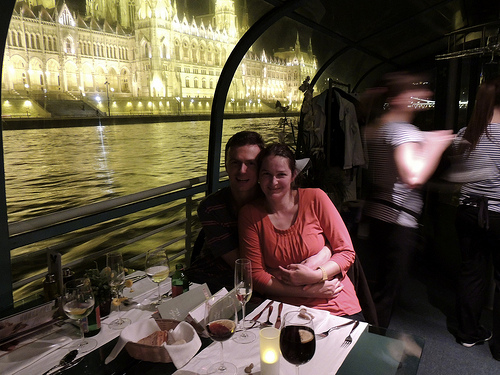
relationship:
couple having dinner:
[188, 130, 365, 323] [168, 260, 376, 374]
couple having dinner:
[188, 130, 365, 323] [101, 237, 249, 335]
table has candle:
[3, 255, 428, 372] [254, 323, 287, 374]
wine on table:
[280, 306, 319, 374] [3, 255, 428, 372]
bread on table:
[119, 313, 203, 367] [3, 255, 428, 372]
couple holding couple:
[188, 130, 365, 323] [188, 130, 365, 323]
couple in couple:
[188, 130, 365, 323] [188, 130, 365, 323]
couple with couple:
[188, 130, 365, 323] [188, 130, 365, 323]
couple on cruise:
[188, 130, 365, 323] [3, 3, 500, 374]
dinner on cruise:
[3, 255, 428, 372] [3, 3, 500, 374]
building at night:
[2, 1, 324, 122] [3, 3, 500, 374]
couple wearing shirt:
[188, 130, 365, 323] [239, 183, 367, 317]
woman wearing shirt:
[447, 76, 498, 348] [448, 119, 499, 225]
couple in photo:
[188, 130, 365, 323] [3, 3, 500, 374]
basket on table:
[119, 313, 203, 367] [3, 255, 428, 372]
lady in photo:
[349, 69, 465, 338] [3, 3, 500, 374]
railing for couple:
[1, 168, 229, 331] [188, 130, 365, 323]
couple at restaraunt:
[188, 130, 365, 323] [3, 3, 500, 374]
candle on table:
[254, 323, 287, 374] [3, 255, 428, 372]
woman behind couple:
[447, 76, 498, 348] [188, 130, 365, 323]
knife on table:
[252, 292, 273, 321] [3, 255, 428, 372]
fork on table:
[340, 321, 365, 348] [3, 255, 428, 372]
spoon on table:
[261, 299, 276, 326] [3, 255, 428, 372]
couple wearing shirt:
[188, 130, 365, 323] [193, 181, 265, 281]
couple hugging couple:
[188, 130, 365, 323] [188, 130, 365, 323]